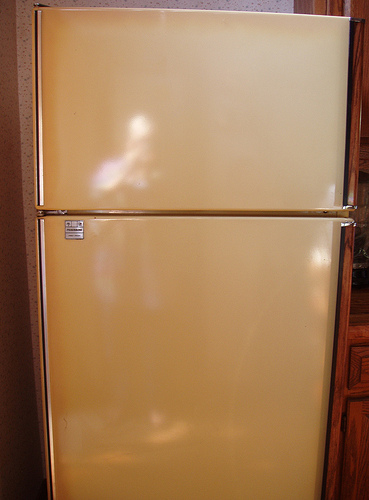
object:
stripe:
[37, 8, 44, 206]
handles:
[343, 15, 364, 206]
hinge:
[38, 206, 75, 220]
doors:
[38, 8, 352, 209]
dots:
[17, 58, 20, 62]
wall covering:
[11, 0, 294, 478]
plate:
[65, 219, 83, 238]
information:
[65, 228, 82, 230]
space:
[41, 209, 342, 217]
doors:
[38, 214, 341, 499]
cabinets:
[340, 397, 369, 499]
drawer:
[347, 345, 369, 391]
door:
[340, 397, 368, 499]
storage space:
[343, 19, 353, 207]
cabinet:
[350, 0, 369, 172]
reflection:
[65, 102, 202, 479]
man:
[59, 93, 182, 239]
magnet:
[64, 219, 84, 237]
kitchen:
[0, 0, 369, 499]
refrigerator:
[33, 13, 357, 498]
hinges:
[340, 201, 352, 209]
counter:
[348, 286, 369, 358]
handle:
[319, 223, 344, 498]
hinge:
[340, 409, 346, 432]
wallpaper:
[0, 3, 43, 499]